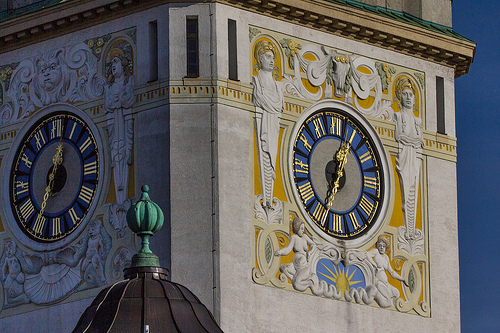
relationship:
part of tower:
[58, 181, 228, 331] [1, 0, 499, 332]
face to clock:
[283, 114, 392, 244] [291, 106, 385, 240]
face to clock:
[17, 109, 103, 249] [7, 108, 101, 242]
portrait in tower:
[249, 24, 431, 320] [1, 0, 499, 332]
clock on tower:
[291, 106, 385, 240] [1, 0, 499, 332]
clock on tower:
[7, 108, 101, 242] [1, 0, 499, 332]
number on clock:
[328, 115, 342, 137] [291, 106, 385, 240]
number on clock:
[349, 127, 358, 146] [291, 106, 385, 240]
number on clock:
[359, 148, 375, 163] [291, 106, 385, 240]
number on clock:
[361, 173, 379, 193] [291, 106, 385, 240]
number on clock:
[359, 195, 376, 215] [291, 106, 385, 240]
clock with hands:
[291, 106, 385, 240] [320, 141, 352, 223]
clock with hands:
[7, 108, 101, 242] [32, 140, 64, 231]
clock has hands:
[291, 106, 385, 240] [320, 141, 352, 223]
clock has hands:
[7, 108, 101, 242] [32, 140, 64, 231]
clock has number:
[291, 106, 385, 240] [328, 115, 342, 137]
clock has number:
[291, 106, 385, 240] [349, 127, 358, 146]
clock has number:
[291, 106, 385, 240] [359, 148, 375, 163]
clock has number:
[291, 106, 385, 240] [361, 173, 379, 193]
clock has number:
[291, 106, 385, 240] [359, 195, 376, 215]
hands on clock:
[320, 141, 352, 223] [291, 106, 385, 240]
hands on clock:
[32, 140, 64, 231] [7, 108, 101, 242]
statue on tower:
[275, 214, 319, 294] [1, 0, 499, 332]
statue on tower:
[367, 235, 413, 310] [1, 0, 499, 332]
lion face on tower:
[31, 47, 75, 103] [1, 0, 499, 332]